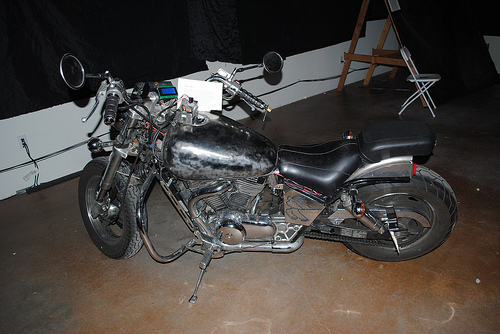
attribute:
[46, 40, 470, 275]
motorcycle — parked 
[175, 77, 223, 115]
paper — white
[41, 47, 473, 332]
motorcycle — padded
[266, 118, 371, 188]
seat — black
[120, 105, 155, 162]
wires — jumble  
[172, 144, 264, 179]
fuel tank — Metallic 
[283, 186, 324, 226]
brown panel — brown 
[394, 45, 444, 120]
chair — white, folding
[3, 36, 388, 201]
panel — white, long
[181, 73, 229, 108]
paper — white, propped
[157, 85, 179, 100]
cellphone — green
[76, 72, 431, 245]
bike — little, black 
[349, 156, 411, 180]
tire panel — twisted, black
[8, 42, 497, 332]
floor — dirty, brown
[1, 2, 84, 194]
wall — white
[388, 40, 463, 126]
folding chair — small, white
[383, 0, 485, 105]
wood surface — slanted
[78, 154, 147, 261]
wheel — black 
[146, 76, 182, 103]
cellphone — green 